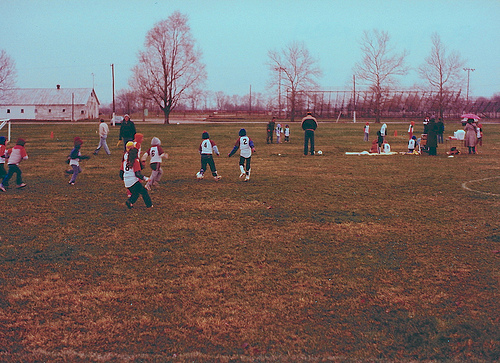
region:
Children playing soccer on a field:
[0, 109, 486, 209]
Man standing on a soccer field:
[298, 103, 319, 155]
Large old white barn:
[0, 85, 100, 124]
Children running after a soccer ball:
[0, 125, 255, 210]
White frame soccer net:
[0, 116, 12, 166]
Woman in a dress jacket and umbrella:
[462, 110, 482, 154]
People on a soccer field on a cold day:
[0, 0, 497, 361]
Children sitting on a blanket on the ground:
[343, 135, 422, 158]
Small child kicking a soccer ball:
[192, 125, 222, 182]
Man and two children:
[263, 112, 292, 145]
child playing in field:
[4, 133, 29, 191]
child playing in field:
[119, 146, 155, 209]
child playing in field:
[123, 128, 146, 148]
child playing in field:
[141, 129, 173, 194]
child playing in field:
[191, 122, 227, 185]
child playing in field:
[223, 125, 255, 185]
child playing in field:
[401, 135, 421, 157]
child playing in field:
[371, 137, 398, 160]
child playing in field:
[282, 121, 297, 144]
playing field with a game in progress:
[7, 12, 485, 347]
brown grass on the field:
[11, 262, 168, 347]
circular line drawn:
[456, 162, 496, 198]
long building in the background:
[1, 67, 98, 119]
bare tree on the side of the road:
[131, 7, 203, 124]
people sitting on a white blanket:
[341, 132, 398, 157]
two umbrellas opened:
[455, 105, 480, 125]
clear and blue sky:
[1, 5, 127, 55]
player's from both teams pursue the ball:
[46, 125, 257, 215]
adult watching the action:
[115, 108, 137, 139]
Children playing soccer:
[0, 2, 499, 217]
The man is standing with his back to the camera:
[297, 107, 319, 158]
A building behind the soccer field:
[1, 80, 102, 122]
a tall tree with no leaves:
[129, 5, 214, 125]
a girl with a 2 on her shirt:
[227, 126, 258, 181]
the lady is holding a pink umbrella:
[457, 109, 484, 156]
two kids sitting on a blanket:
[367, 135, 394, 164]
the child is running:
[62, 135, 90, 191]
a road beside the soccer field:
[150, 113, 287, 128]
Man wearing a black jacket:
[298, 110, 318, 161]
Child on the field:
[185, 126, 225, 192]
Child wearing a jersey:
[226, 128, 261, 182]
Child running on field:
[53, 129, 97, 188]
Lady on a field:
[455, 108, 486, 160]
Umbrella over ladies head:
[457, 103, 489, 125]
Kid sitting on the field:
[364, 132, 385, 157]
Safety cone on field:
[44, 123, 60, 143]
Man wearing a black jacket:
[111, 111, 143, 157]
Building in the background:
[0, 80, 102, 132]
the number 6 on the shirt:
[149, 148, 156, 158]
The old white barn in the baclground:
[0, 87, 101, 124]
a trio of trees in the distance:
[261, 24, 466, 116]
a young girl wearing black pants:
[113, 147, 160, 216]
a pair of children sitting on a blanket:
[368, 133, 399, 158]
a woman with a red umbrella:
[456, 110, 485, 156]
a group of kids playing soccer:
[1, 127, 269, 199]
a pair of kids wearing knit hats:
[187, 122, 265, 181]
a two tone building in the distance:
[0, 84, 106, 122]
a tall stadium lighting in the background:
[458, 60, 477, 116]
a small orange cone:
[390, 125, 402, 141]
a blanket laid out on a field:
[346, 145, 413, 164]